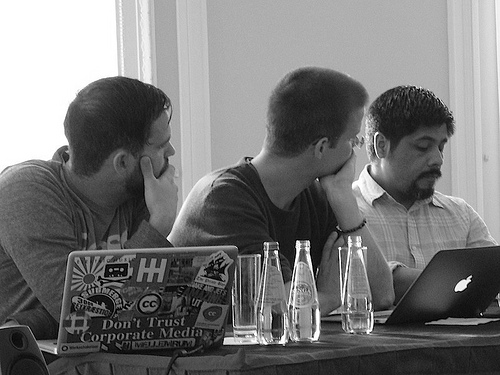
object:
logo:
[453, 275, 473, 293]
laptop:
[322, 244, 500, 326]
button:
[412, 245, 417, 250]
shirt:
[351, 164, 500, 314]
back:
[57, 245, 240, 359]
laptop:
[35, 245, 241, 358]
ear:
[374, 132, 392, 160]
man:
[351, 83, 499, 308]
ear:
[112, 152, 131, 176]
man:
[3, 76, 181, 337]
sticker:
[96, 260, 133, 293]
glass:
[231, 253, 261, 343]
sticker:
[137, 293, 162, 314]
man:
[168, 67, 395, 325]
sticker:
[192, 301, 229, 330]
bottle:
[257, 240, 292, 345]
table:
[36, 310, 498, 374]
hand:
[139, 156, 181, 220]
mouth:
[162, 164, 171, 173]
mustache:
[159, 159, 169, 177]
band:
[335, 219, 366, 234]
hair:
[167, 99, 174, 125]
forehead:
[149, 108, 171, 146]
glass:
[340, 236, 376, 335]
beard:
[407, 168, 443, 200]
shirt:
[165, 155, 338, 328]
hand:
[319, 148, 356, 188]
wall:
[210, 0, 453, 193]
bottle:
[286, 240, 323, 344]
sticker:
[194, 248, 235, 290]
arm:
[320, 185, 398, 312]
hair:
[264, 66, 370, 161]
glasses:
[311, 136, 365, 150]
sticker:
[61, 310, 94, 336]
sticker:
[62, 251, 236, 352]